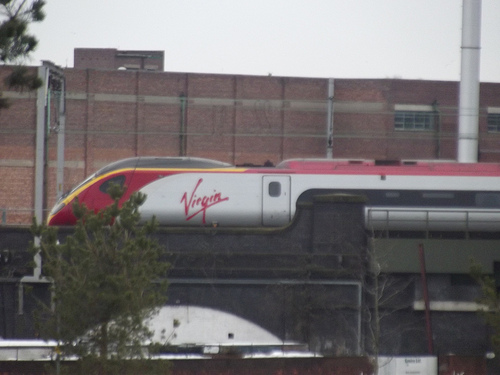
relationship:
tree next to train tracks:
[57, 203, 185, 373] [2, 292, 485, 352]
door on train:
[262, 175, 291, 228] [42, 128, 498, 248]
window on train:
[98, 175, 125, 191] [46, 157, 496, 229]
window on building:
[389, 100, 436, 129] [0, 45, 497, 165]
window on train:
[420, 185, 459, 207] [26, 152, 498, 342]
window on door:
[270, 179, 280, 195] [262, 178, 292, 224]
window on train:
[81, 150, 172, 237] [28, 118, 469, 310]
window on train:
[473, 190, 498, 211] [41, 150, 498, 238]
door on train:
[256, 165, 295, 233] [32, 145, 499, 247]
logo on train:
[180, 178, 230, 223] [41, 150, 498, 238]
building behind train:
[61, 46, 388, 155] [51, 152, 459, 231]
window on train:
[473, 190, 498, 209] [46, 157, 496, 229]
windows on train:
[379, 191, 499, 206] [44, 152, 483, 278]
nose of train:
[45, 156, 134, 228] [41, 150, 498, 238]